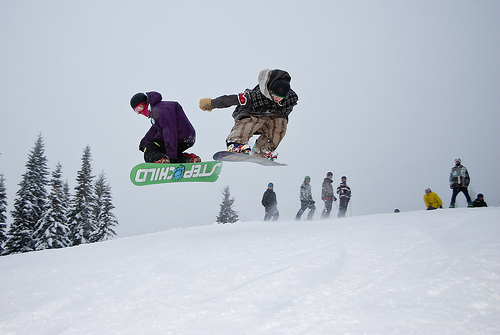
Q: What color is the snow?
A: White.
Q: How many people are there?
A: More than five.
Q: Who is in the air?
A: Two men.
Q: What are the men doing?
A: Snowboarding.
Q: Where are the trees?
A: On the left.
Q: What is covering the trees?
A: Snow.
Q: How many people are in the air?
A: Two.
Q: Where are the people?
A: Mountain.